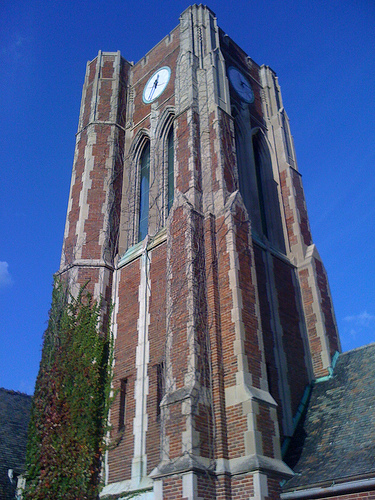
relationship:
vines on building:
[28, 267, 108, 495] [35, 3, 374, 498]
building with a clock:
[35, 3, 374, 498] [225, 63, 255, 105]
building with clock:
[26, 2, 341, 498] [227, 66, 254, 102]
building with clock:
[26, 2, 341, 498] [140, 64, 173, 103]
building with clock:
[69, 7, 349, 334] [225, 61, 258, 105]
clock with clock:
[225, 61, 258, 105] [134, 61, 176, 106]